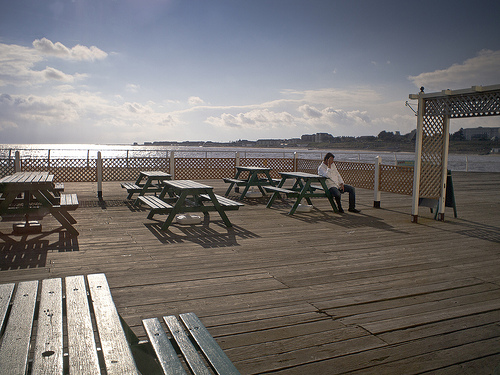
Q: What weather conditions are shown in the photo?
A: It is partly cloudy.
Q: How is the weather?
A: It is partly cloudy.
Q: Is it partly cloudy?
A: Yes, it is partly cloudy.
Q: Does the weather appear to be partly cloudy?
A: Yes, it is partly cloudy.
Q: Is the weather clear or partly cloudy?
A: It is partly cloudy.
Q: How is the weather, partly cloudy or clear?
A: It is partly cloudy.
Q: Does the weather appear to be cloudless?
A: No, it is partly cloudy.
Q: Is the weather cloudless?
A: No, it is partly cloudy.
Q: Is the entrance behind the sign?
A: Yes, the entrance is behind the sign.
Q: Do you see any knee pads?
A: No, there are no knee pads.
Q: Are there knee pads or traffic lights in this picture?
A: No, there are no knee pads or traffic lights.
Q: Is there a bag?
A: No, there are no bags.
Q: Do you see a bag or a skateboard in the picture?
A: No, there are no bags or skateboards.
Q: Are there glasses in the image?
A: No, there are no glasses.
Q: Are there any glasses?
A: No, there are no glasses.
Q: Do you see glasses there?
A: No, there are no glasses.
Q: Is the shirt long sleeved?
A: Yes, the shirt is long sleeved.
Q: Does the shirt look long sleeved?
A: Yes, the shirt is long sleeved.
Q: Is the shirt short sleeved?
A: No, the shirt is long sleeved.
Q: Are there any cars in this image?
A: No, there are no cars.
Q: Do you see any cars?
A: No, there are no cars.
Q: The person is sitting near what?
A: The person is sitting by the water.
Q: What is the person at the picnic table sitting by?
A: The person is sitting by the water.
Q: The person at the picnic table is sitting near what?
A: The person is sitting by the water.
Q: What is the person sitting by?
A: The person is sitting by the water.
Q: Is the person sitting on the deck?
A: Yes, the person is sitting on the deck.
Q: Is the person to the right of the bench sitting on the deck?
A: Yes, the person is sitting on the deck.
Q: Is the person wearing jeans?
A: Yes, the person is wearing jeans.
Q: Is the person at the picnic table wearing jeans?
A: Yes, the person is wearing jeans.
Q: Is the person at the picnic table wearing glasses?
A: No, the person is wearing jeans.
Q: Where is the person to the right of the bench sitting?
A: The person is sitting at the picnic table.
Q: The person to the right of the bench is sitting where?
A: The person is sitting at the picnic table.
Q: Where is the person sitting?
A: The person is sitting at the picnic table.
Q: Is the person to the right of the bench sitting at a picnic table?
A: Yes, the person is sitting at a picnic table.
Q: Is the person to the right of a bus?
A: No, the person is to the right of a bench.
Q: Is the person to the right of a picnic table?
A: Yes, the person is to the right of a picnic table.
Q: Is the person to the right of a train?
A: No, the person is to the right of a picnic table.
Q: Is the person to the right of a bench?
A: Yes, the person is to the right of a bench.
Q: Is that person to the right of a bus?
A: No, the person is to the right of a bench.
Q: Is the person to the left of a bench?
A: No, the person is to the right of a bench.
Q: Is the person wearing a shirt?
A: Yes, the person is wearing a shirt.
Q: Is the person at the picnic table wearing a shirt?
A: Yes, the person is wearing a shirt.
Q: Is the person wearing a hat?
A: No, the person is wearing a shirt.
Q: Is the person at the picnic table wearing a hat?
A: No, the person is wearing a shirt.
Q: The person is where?
A: The person is at the picnic table.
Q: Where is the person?
A: The person is at the picnic table.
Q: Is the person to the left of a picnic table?
A: No, the person is to the right of a picnic table.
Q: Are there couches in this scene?
A: No, there are no couches.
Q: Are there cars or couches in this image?
A: No, there are no couches or cars.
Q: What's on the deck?
A: The picnic table is on the deck.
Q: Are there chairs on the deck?
A: No, there is a picnic table on the deck.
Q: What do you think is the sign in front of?
A: The sign is in front of the entrance.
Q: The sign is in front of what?
A: The sign is in front of the entrance.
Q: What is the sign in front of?
A: The sign is in front of the entrance.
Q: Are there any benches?
A: Yes, there is a bench.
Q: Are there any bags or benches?
A: Yes, there is a bench.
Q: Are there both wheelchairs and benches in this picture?
A: No, there is a bench but no wheelchairs.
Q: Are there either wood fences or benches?
A: Yes, there is a wood bench.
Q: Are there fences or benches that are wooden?
A: Yes, the bench is wooden.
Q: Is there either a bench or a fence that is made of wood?
A: Yes, the bench is made of wood.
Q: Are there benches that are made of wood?
A: Yes, there is a bench that is made of wood.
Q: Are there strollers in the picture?
A: No, there are no strollers.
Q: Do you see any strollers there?
A: No, there are no strollers.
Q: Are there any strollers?
A: No, there are no strollers.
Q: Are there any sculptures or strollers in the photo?
A: No, there are no strollers or sculptures.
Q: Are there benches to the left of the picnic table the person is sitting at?
A: Yes, there is a bench to the left of the picnic table.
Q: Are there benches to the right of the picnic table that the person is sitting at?
A: No, the bench is to the left of the picnic table.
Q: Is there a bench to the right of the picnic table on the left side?
A: Yes, there is a bench to the right of the picnic table.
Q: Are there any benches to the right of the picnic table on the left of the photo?
A: Yes, there is a bench to the right of the picnic table.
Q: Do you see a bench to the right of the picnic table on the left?
A: Yes, there is a bench to the right of the picnic table.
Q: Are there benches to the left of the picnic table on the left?
A: No, the bench is to the right of the picnic table.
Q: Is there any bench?
A: Yes, there is a bench.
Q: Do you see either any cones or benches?
A: Yes, there is a bench.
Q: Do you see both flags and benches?
A: No, there is a bench but no flags.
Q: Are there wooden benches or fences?
A: Yes, there is a wood bench.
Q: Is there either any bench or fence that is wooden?
A: Yes, the bench is wooden.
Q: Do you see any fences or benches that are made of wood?
A: Yes, the bench is made of wood.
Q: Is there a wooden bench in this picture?
A: Yes, there is a wood bench.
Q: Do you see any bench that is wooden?
A: Yes, there is a wood bench.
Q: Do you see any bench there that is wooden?
A: Yes, there is a bench that is wooden.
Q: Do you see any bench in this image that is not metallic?
A: Yes, there is a wooden bench.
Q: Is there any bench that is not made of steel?
A: Yes, there is a bench that is made of wood.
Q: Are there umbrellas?
A: No, there are no umbrellas.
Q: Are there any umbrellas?
A: No, there are no umbrellas.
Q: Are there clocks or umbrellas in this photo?
A: No, there are no umbrellas or clocks.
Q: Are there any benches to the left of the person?
A: Yes, there is a bench to the left of the person.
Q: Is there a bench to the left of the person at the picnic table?
A: Yes, there is a bench to the left of the person.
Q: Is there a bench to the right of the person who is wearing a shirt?
A: No, the bench is to the left of the person.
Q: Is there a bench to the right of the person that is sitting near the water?
A: No, the bench is to the left of the person.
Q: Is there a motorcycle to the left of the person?
A: No, there is a bench to the left of the person.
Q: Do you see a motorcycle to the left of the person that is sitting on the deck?
A: No, there is a bench to the left of the person.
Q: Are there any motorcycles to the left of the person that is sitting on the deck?
A: No, there is a bench to the left of the person.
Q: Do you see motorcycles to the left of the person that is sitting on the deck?
A: No, there is a bench to the left of the person.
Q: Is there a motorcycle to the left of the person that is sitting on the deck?
A: No, there is a bench to the left of the person.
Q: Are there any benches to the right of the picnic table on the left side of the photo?
A: Yes, there is a bench to the right of the picnic table.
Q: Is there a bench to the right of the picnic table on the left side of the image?
A: Yes, there is a bench to the right of the picnic table.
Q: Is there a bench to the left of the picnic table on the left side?
A: No, the bench is to the right of the picnic table.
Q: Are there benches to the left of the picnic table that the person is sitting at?
A: Yes, there is a bench to the left of the picnic table.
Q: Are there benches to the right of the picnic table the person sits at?
A: No, the bench is to the left of the picnic table.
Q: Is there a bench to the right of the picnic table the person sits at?
A: No, the bench is to the left of the picnic table.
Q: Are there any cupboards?
A: No, there are no cupboards.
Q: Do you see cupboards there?
A: No, there are no cupboards.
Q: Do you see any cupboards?
A: No, there are no cupboards.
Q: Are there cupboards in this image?
A: No, there are no cupboards.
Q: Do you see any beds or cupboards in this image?
A: No, there are no cupboards or beds.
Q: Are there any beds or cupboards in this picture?
A: No, there are no cupboards or beds.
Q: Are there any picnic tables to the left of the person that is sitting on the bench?
A: Yes, there is a picnic table to the left of the person.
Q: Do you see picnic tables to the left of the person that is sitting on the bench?
A: Yes, there is a picnic table to the left of the person.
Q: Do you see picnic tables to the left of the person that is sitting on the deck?
A: Yes, there is a picnic table to the left of the person.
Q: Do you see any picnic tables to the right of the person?
A: No, the picnic table is to the left of the person.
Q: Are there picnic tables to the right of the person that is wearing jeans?
A: No, the picnic table is to the left of the person.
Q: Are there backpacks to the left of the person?
A: No, there is a picnic table to the left of the person.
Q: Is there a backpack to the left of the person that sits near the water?
A: No, there is a picnic table to the left of the person.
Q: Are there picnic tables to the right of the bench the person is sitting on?
A: No, the picnic table is to the left of the bench.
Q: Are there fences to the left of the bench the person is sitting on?
A: No, there is a picnic table to the left of the bench.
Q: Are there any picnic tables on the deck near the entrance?
A: Yes, there is a picnic table on the deck.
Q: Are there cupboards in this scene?
A: No, there are no cupboards.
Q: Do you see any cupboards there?
A: No, there are no cupboards.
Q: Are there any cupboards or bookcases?
A: No, there are no cupboards or bookcases.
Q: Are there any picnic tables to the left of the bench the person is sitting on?
A: Yes, there is a picnic table to the left of the bench.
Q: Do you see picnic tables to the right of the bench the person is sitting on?
A: No, the picnic table is to the left of the bench.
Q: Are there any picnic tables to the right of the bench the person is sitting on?
A: No, the picnic table is to the left of the bench.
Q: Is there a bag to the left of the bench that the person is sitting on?
A: No, there is a picnic table to the left of the bench.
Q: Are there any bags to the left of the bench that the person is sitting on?
A: No, there is a picnic table to the left of the bench.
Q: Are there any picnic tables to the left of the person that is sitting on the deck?
A: Yes, there is a picnic table to the left of the person.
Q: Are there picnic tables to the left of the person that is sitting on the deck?
A: Yes, there is a picnic table to the left of the person.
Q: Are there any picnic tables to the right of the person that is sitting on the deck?
A: No, the picnic table is to the left of the person.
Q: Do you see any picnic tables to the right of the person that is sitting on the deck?
A: No, the picnic table is to the left of the person.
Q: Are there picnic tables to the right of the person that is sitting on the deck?
A: No, the picnic table is to the left of the person.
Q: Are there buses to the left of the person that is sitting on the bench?
A: No, there is a picnic table to the left of the person.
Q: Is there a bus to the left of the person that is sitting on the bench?
A: No, there is a picnic table to the left of the person.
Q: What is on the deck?
A: The picnic table is on the deck.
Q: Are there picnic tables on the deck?
A: Yes, there is a picnic table on the deck.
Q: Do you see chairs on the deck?
A: No, there is a picnic table on the deck.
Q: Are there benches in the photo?
A: Yes, there is a bench.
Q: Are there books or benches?
A: Yes, there is a bench.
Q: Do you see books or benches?
A: Yes, there is a bench.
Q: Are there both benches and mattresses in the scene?
A: No, there is a bench but no mattresses.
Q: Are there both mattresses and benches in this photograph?
A: No, there is a bench but no mattresses.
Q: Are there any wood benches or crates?
A: Yes, there is a wood bench.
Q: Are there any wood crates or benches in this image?
A: Yes, there is a wood bench.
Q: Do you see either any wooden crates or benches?
A: Yes, there is a wood bench.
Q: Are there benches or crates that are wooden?
A: Yes, the bench is wooden.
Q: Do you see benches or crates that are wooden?
A: Yes, the bench is wooden.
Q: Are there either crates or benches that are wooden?
A: Yes, the bench is wooden.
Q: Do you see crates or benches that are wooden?
A: Yes, the bench is wooden.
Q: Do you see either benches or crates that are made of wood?
A: Yes, the bench is made of wood.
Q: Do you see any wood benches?
A: Yes, there is a wood bench.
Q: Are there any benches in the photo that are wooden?
A: Yes, there is a bench that is wooden.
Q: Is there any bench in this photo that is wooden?
A: Yes, there is a bench that is wooden.